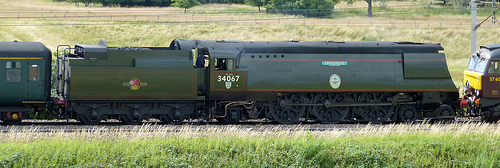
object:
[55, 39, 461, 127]
train car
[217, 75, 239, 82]
number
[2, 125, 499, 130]
train track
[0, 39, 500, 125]
train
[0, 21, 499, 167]
ground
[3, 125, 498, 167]
tall grass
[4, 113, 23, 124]
wheels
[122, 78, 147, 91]
emblem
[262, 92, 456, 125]
metal wheel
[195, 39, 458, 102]
train engine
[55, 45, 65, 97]
ladder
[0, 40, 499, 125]
car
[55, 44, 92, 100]
end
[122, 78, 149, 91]
logo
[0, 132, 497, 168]
grass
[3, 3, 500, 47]
grass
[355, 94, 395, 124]
wheel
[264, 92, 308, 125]
wheel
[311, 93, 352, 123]
wheel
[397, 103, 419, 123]
wheel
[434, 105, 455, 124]
wheel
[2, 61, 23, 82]
window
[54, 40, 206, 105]
train car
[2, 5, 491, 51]
pasture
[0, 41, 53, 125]
train cars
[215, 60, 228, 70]
person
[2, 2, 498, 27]
fence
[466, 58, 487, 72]
windshield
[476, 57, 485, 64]
wiper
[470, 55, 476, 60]
wiper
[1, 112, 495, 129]
railroad line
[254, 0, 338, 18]
trees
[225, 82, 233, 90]
shield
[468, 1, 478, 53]
pole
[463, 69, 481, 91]
paint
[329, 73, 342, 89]
design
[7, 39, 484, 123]
railroad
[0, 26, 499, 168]
field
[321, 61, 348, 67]
text